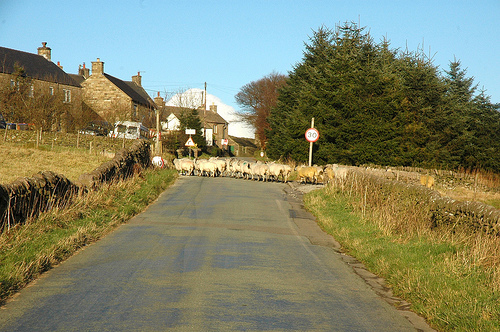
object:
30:
[306, 132, 322, 138]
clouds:
[160, 6, 280, 58]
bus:
[106, 121, 150, 140]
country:
[2, 0, 498, 330]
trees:
[269, 21, 498, 174]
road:
[9, 172, 426, 329]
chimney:
[131, 71, 142, 87]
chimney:
[36, 41, 51, 61]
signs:
[184, 130, 198, 157]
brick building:
[80, 57, 160, 139]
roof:
[101, 72, 156, 108]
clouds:
[171, 84, 268, 148]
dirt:
[209, 213, 261, 270]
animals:
[150, 155, 351, 185]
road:
[1, 149, 438, 330]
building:
[0, 41, 83, 134]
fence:
[0, 138, 150, 237]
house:
[152, 92, 231, 157]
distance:
[30, 15, 499, 190]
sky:
[0, 0, 500, 135]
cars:
[78, 120, 113, 136]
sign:
[305, 127, 320, 142]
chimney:
[91, 57, 105, 74]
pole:
[307, 116, 317, 168]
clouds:
[61, 0, 131, 61]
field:
[303, 167, 493, 319]